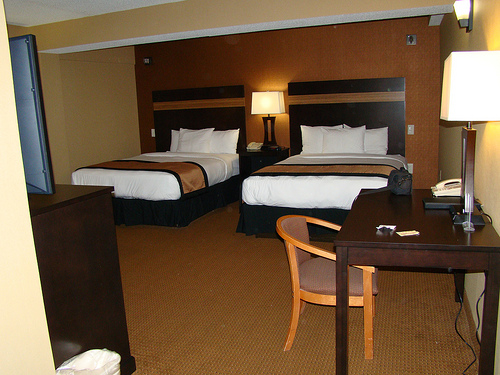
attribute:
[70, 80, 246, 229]
bed — queen size, full size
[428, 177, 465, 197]
phone — off white, noticeable, perceivable, beige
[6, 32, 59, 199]
television — flat screen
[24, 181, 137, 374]
tv stand — brown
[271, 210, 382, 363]
chair — wooden, cushioned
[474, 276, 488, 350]
cord — black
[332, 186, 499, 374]
table — brown, perceptible, perceivable, seeable, detectable, in sight, dark brown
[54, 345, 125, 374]
trash can — white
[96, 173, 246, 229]
bedskirt — black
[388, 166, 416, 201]
purse — gray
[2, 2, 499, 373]
room — nicely decorated, neat, clean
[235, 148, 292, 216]
nightstand — wooden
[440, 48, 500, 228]
lamp — on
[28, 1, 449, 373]
wall — yellow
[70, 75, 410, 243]
beds — identical